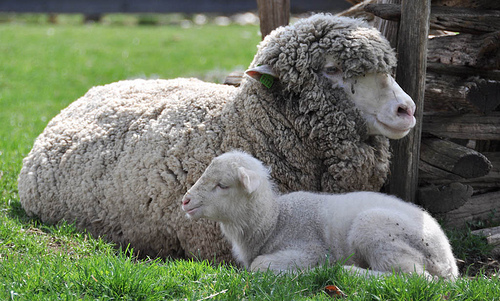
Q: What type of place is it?
A: It is a field.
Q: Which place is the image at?
A: It is at the field.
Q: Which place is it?
A: It is a field.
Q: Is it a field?
A: Yes, it is a field.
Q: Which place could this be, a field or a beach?
A: It is a field.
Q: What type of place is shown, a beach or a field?
A: It is a field.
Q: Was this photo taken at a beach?
A: No, the picture was taken in a field.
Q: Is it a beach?
A: No, it is a field.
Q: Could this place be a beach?
A: No, it is a field.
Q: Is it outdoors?
A: Yes, it is outdoors.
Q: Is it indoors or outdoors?
A: It is outdoors.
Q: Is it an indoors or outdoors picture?
A: It is outdoors.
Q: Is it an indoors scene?
A: No, it is outdoors.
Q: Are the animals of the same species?
A: No, there are both sheep and cows.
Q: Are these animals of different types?
A: Yes, they are sheep and cows.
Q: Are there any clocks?
A: No, there are no clocks.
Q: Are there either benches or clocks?
A: No, there are no clocks or benches.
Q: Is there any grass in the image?
A: Yes, there is grass.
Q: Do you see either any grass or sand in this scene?
A: Yes, there is grass.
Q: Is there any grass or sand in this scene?
A: Yes, there is grass.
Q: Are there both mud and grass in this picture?
A: No, there is grass but no mud.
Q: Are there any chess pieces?
A: No, there are no chess pieces.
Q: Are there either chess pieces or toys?
A: No, there are no chess pieces or toys.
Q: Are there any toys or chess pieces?
A: No, there are no chess pieces or toys.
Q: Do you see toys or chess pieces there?
A: No, there are no chess pieces or toys.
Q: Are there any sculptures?
A: No, there are no sculptures.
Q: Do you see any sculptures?
A: No, there are no sculptures.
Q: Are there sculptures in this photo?
A: No, there are no sculptures.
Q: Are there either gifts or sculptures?
A: No, there are no sculptures or gifts.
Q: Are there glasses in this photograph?
A: No, there are no glasses.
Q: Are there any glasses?
A: No, there are no glasses.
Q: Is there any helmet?
A: No, there are no helmets.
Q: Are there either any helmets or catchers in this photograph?
A: No, there are no helmets or catchers.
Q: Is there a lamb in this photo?
A: Yes, there is a lamb.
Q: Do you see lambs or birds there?
A: Yes, there is a lamb.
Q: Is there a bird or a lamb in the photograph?
A: Yes, there is a lamb.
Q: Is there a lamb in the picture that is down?
A: Yes, there is a lamb that is down.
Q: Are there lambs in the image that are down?
A: Yes, there is a lamb that is down.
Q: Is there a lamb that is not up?
A: Yes, there is a lamb that is down.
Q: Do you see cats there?
A: No, there are no cats.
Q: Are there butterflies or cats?
A: No, there are no cats or butterflies.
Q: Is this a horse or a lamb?
A: This is a lamb.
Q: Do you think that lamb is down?
A: Yes, the lamb is down.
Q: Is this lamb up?
A: No, the lamb is down.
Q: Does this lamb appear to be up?
A: No, the lamb is down.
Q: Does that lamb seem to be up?
A: No, the lamb is down.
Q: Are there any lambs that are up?
A: No, there is a lamb but it is down.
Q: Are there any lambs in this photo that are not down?
A: No, there is a lamb but it is down.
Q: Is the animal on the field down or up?
A: The lamb is down.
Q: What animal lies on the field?
A: The lamb lies on the field.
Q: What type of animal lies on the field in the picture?
A: The animal is a lamb.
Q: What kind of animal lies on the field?
A: The animal is a lamb.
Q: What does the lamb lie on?
A: The lamb lies on the field.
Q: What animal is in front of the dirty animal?
A: The lamb is in front of the sheep.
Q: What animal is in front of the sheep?
A: The lamb is in front of the sheep.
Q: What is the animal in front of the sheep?
A: The animal is a lamb.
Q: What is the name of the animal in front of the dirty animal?
A: The animal is a lamb.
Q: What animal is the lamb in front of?
A: The lamb is in front of the sheep.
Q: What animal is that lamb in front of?
A: The lamb is in front of the sheep.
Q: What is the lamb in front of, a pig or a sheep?
A: The lamb is in front of a sheep.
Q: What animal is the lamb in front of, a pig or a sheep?
A: The lamb is in front of a sheep.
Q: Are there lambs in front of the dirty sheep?
A: Yes, there is a lamb in front of the sheep.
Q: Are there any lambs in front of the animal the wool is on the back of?
A: Yes, there is a lamb in front of the sheep.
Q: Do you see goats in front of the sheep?
A: No, there is a lamb in front of the sheep.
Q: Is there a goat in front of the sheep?
A: No, there is a lamb in front of the sheep.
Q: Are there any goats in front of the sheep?
A: No, there is a lamb in front of the sheep.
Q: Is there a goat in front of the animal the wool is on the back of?
A: No, there is a lamb in front of the sheep.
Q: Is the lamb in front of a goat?
A: No, the lamb is in front of the sheep.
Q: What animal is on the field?
A: The animal is a lamb.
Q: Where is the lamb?
A: The lamb is on the field.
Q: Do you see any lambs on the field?
A: Yes, there is a lamb on the field.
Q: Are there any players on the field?
A: No, there is a lamb on the field.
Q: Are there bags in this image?
A: No, there are no bags.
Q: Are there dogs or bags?
A: No, there are no bags or dogs.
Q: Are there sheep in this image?
A: Yes, there is a sheep.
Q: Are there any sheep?
A: Yes, there is a sheep.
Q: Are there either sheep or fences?
A: Yes, there is a sheep.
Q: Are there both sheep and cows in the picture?
A: Yes, there are both a sheep and a cow.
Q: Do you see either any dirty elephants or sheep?
A: Yes, there is a dirty sheep.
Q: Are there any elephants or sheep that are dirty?
A: Yes, the sheep is dirty.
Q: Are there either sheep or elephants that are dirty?
A: Yes, the sheep is dirty.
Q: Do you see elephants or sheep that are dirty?
A: Yes, the sheep is dirty.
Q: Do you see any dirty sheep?
A: Yes, there is a dirty sheep.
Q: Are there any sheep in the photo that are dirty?
A: Yes, there is a sheep that is dirty.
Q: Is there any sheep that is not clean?
A: Yes, there is a dirty sheep.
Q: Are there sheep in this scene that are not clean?
A: Yes, there is a dirty sheep.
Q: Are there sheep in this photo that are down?
A: Yes, there is a sheep that is down.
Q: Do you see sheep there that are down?
A: Yes, there is a sheep that is down.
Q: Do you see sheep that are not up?
A: Yes, there is a sheep that is down .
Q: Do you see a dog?
A: No, there are no dogs.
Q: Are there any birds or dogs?
A: No, there are no dogs or birds.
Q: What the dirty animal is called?
A: The animal is a sheep.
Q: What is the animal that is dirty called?
A: The animal is a sheep.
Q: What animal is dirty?
A: The animal is a sheep.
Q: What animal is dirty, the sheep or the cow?
A: The sheep is dirty.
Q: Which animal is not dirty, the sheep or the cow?
A: The cow is not dirty.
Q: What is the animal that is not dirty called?
A: The animal is a cow.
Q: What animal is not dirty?
A: The animal is a cow.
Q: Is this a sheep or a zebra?
A: This is a sheep.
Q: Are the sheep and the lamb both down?
A: Yes, both the sheep and the lamb are down.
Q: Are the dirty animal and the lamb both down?
A: Yes, both the sheep and the lamb are down.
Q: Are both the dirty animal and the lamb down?
A: Yes, both the sheep and the lamb are down.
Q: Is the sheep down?
A: Yes, the sheep is down.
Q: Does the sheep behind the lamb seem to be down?
A: Yes, the sheep is down.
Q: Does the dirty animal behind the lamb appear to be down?
A: Yes, the sheep is down.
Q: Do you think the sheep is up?
A: No, the sheep is down.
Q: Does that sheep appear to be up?
A: No, the sheep is down.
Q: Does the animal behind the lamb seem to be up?
A: No, the sheep is down.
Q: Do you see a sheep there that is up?
A: No, there is a sheep but it is down.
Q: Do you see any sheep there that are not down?
A: No, there is a sheep but it is down.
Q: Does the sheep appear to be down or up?
A: The sheep is down.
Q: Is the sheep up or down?
A: The sheep is down.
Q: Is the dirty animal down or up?
A: The sheep is down.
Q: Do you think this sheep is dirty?
A: Yes, the sheep is dirty.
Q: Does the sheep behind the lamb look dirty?
A: Yes, the sheep is dirty.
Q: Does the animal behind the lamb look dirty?
A: Yes, the sheep is dirty.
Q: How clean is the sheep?
A: The sheep is dirty.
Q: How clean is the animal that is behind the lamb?
A: The sheep is dirty.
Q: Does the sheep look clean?
A: No, the sheep is dirty.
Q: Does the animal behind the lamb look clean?
A: No, the sheep is dirty.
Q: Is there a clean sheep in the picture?
A: No, there is a sheep but it is dirty.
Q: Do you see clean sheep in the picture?
A: No, there is a sheep but it is dirty.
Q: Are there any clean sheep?
A: No, there is a sheep but it is dirty.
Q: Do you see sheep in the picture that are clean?
A: No, there is a sheep but it is dirty.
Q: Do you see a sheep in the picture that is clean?
A: No, there is a sheep but it is dirty.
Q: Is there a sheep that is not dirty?
A: No, there is a sheep but it is dirty.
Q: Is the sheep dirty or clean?
A: The sheep is dirty.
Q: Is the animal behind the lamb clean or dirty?
A: The sheep is dirty.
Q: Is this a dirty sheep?
A: Yes, this is a dirty sheep.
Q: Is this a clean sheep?
A: No, this is a dirty sheep.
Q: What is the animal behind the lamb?
A: The animal is a sheep.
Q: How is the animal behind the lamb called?
A: The animal is a sheep.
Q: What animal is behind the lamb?
A: The animal is a sheep.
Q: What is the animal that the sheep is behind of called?
A: The animal is a lamb.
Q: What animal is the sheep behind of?
A: The sheep is behind the lamb.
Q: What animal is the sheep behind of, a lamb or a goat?
A: The sheep is behind a lamb.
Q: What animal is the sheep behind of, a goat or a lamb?
A: The sheep is behind a lamb.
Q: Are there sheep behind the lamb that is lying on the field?
A: Yes, there is a sheep behind the lamb.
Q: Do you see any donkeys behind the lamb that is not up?
A: No, there is a sheep behind the lamb.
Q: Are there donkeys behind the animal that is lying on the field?
A: No, there is a sheep behind the lamb.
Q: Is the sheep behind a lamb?
A: Yes, the sheep is behind a lamb.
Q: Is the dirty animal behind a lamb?
A: Yes, the sheep is behind a lamb.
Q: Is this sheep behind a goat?
A: No, the sheep is behind a lamb.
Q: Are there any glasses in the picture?
A: No, there are no glasses.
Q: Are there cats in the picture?
A: No, there are no cats.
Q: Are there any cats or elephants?
A: No, there are no cats or elephants.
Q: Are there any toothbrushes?
A: No, there are no toothbrushes.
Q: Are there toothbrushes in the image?
A: No, there are no toothbrushes.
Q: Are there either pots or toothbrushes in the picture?
A: No, there are no toothbrushes or pots.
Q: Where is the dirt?
A: The dirt is in the field.